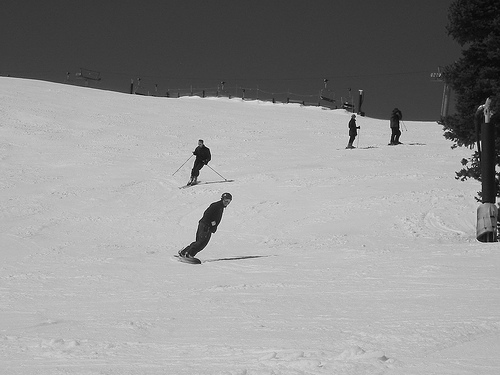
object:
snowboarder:
[174, 192, 234, 265]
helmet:
[221, 192, 232, 198]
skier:
[345, 115, 362, 151]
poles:
[356, 129, 360, 148]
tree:
[440, 5, 499, 204]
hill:
[1, 79, 499, 375]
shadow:
[202, 253, 267, 260]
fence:
[119, 76, 345, 110]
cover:
[470, 104, 500, 244]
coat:
[197, 198, 225, 234]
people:
[387, 106, 404, 147]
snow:
[4, 155, 173, 374]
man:
[174, 192, 232, 265]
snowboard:
[174, 251, 204, 266]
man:
[170, 139, 229, 189]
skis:
[177, 179, 203, 191]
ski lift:
[65, 67, 175, 95]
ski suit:
[347, 119, 361, 146]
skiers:
[170, 139, 231, 190]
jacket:
[348, 119, 358, 135]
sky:
[1, 3, 322, 68]